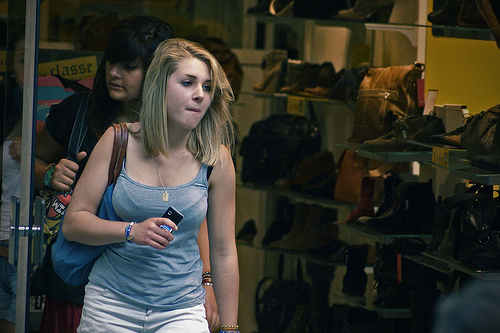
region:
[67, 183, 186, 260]
the girl is holding a cell phone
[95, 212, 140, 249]
the girl is wearing a bracelet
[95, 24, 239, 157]
the girl has blonde hair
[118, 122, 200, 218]
the girl is wearing a gold necklace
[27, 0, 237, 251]
a woman is behind the girl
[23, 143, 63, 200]
the woman is wearing a green watch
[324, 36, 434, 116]
the bag is brown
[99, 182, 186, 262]
the phone is on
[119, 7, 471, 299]
the store sells bags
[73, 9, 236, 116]
the woman has dark hair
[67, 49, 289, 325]
a woman holding a cell phone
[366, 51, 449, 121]
a brown leather purse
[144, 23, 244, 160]
a woman with blonde hair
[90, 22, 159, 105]
a woman with black hair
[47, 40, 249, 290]
a woman carrying a blue purse on shoulder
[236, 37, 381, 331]
racks of new purses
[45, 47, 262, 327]
a woman wearing a blue tank top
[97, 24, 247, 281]
a woman wearing a bracelet on her wrist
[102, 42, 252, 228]
a woman wearing a gold necklace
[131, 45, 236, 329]
a woman wearing white pants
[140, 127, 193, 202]
a necklace around the womans neck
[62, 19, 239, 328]
a woman wearing a blue shirt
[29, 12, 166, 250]
a woman with black hair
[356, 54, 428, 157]
a beige bag on the shelf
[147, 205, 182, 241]
the cellphone in the woman's hand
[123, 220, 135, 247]
a bracelet around the woman's wrist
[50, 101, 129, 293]
a blue purse with a brown strap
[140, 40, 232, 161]
the woman's blond hair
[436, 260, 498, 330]
someone's head out of focus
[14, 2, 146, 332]
a door being opened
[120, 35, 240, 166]
girl with blond hair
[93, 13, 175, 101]
girl with black hair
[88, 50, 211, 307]
girl with blue tank top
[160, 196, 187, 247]
girl holds phone in right hand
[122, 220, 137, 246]
girl wears blue bracelet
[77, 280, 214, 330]
girl wears white pants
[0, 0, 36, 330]
door is open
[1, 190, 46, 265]
silver door handle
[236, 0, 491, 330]
shelves of purses and shoes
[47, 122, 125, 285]
girl carries blue bag on shoulder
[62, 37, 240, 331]
a young caucasian girl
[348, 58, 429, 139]
a brown purse on a shelf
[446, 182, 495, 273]
a black purse on a shelf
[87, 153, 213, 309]
a grey tank top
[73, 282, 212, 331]
a pair of white shorts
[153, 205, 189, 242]
a cell phone in a hand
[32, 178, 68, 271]
a multi-colored hand bag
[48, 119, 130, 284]
a blue bag with a brown strap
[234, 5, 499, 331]
a set of glass shelves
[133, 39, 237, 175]
blonde hair